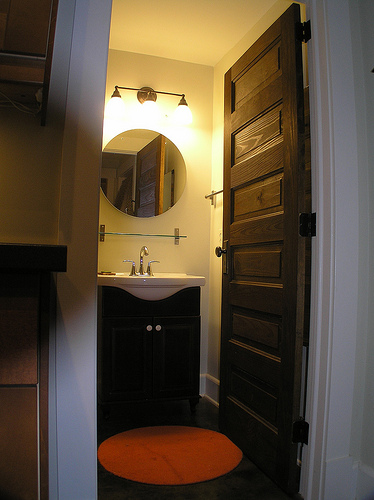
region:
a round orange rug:
[123, 401, 208, 493]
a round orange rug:
[166, 402, 209, 492]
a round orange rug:
[154, 423, 192, 475]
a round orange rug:
[134, 424, 182, 492]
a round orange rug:
[198, 414, 259, 496]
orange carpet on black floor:
[107, 427, 258, 496]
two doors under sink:
[103, 310, 208, 412]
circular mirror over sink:
[91, 121, 190, 220]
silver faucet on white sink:
[102, 238, 175, 279]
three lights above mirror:
[108, 73, 199, 147]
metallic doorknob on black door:
[195, 228, 249, 293]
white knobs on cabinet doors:
[127, 320, 196, 348]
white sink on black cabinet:
[100, 261, 200, 312]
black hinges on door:
[285, 191, 338, 465]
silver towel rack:
[84, 213, 197, 252]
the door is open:
[213, 296, 250, 417]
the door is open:
[213, 271, 269, 466]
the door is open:
[218, 331, 253, 448]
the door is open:
[233, 379, 250, 462]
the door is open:
[219, 366, 248, 474]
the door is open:
[279, 349, 284, 470]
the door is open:
[232, 262, 288, 490]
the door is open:
[264, 366, 312, 490]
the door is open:
[217, 337, 303, 495]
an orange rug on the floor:
[110, 388, 205, 496]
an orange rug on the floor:
[141, 430, 191, 496]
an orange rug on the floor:
[181, 412, 243, 492]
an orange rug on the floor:
[194, 470, 208, 487]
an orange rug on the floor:
[177, 447, 227, 494]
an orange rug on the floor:
[160, 423, 210, 495]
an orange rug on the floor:
[149, 425, 181, 466]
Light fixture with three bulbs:
[108, 65, 207, 130]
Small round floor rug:
[98, 421, 248, 497]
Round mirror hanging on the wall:
[101, 109, 199, 219]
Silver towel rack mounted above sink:
[100, 213, 202, 286]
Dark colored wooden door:
[225, 110, 293, 373]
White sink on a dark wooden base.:
[100, 239, 211, 424]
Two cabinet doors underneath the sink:
[100, 315, 204, 402]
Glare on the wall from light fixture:
[171, 106, 218, 167]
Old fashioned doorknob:
[209, 227, 232, 279]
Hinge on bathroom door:
[290, 191, 323, 255]